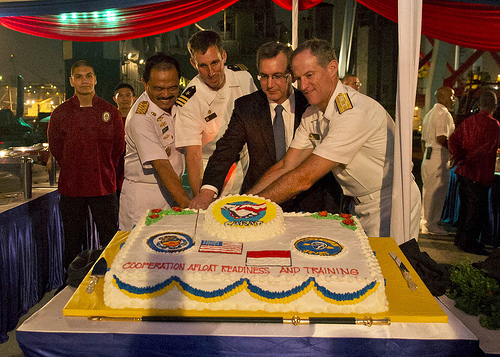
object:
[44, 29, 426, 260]
military members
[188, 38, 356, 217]
men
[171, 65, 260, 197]
uniform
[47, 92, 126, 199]
jacket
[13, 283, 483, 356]
cloth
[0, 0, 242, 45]
sash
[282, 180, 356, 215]
suit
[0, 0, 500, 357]
spectacle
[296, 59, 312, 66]
skin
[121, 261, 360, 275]
writing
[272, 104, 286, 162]
neck tie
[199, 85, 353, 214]
coat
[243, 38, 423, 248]
man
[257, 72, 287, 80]
glasses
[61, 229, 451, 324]
platter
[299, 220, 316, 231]
frosting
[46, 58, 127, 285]
worker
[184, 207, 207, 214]
knife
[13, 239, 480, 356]
table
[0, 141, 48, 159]
food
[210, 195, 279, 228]
emblems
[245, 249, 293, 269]
decoration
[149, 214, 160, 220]
flowers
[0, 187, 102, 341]
skirt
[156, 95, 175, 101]
mustache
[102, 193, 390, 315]
cake